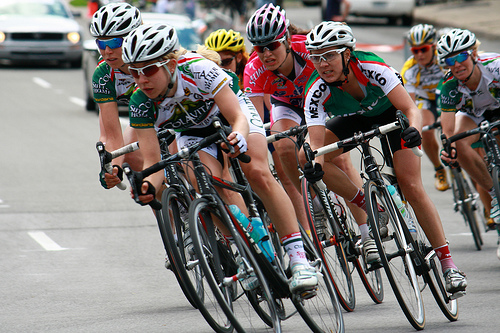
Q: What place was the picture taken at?
A: It was taken at the road.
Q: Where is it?
A: This is at the road.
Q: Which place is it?
A: It is a road.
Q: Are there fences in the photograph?
A: No, there are no fences.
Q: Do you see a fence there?
A: No, there are no fences.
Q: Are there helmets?
A: Yes, there is a helmet.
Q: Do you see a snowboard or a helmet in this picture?
A: Yes, there is a helmet.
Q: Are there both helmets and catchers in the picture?
A: No, there is a helmet but no catchers.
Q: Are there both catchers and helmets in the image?
A: No, there is a helmet but no catchers.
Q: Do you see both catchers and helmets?
A: No, there is a helmet but no catchers.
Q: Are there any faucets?
A: No, there are no faucets.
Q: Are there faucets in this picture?
A: No, there are no faucets.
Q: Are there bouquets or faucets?
A: No, there are no faucets or bouquets.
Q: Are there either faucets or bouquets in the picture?
A: No, there are no faucets or bouquets.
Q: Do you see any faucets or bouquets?
A: No, there are no faucets or bouquets.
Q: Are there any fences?
A: No, there are no fences.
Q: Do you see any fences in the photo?
A: No, there are no fences.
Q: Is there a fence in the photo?
A: No, there are no fences.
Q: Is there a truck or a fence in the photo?
A: No, there are no fences or trucks.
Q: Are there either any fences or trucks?
A: No, there are no fences or trucks.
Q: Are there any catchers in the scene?
A: No, there are no catchers.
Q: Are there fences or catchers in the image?
A: No, there are no catchers or fences.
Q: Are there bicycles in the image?
A: Yes, there is a bicycle.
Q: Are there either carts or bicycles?
A: Yes, there is a bicycle.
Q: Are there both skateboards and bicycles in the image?
A: No, there is a bicycle but no skateboards.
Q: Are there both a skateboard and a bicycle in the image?
A: No, there is a bicycle but no skateboards.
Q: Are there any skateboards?
A: No, there are no skateboards.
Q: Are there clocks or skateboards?
A: No, there are no skateboards or clocks.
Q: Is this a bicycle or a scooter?
A: This is a bicycle.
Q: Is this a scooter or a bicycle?
A: This is a bicycle.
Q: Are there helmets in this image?
A: Yes, there is a helmet.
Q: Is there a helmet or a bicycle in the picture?
A: Yes, there is a helmet.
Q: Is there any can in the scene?
A: No, there are no cans.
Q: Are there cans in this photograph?
A: No, there are no cans.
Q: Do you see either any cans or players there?
A: No, there are no cans or players.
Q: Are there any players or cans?
A: No, there are no cans or players.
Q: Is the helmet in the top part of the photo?
A: Yes, the helmet is in the top of the image.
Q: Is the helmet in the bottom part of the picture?
A: No, the helmet is in the top of the image.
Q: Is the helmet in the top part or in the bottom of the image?
A: The helmet is in the top of the image.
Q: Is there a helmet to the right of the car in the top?
A: Yes, there is a helmet to the right of the car.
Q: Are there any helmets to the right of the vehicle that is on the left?
A: Yes, there is a helmet to the right of the car.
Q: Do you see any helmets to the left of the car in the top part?
A: No, the helmet is to the right of the car.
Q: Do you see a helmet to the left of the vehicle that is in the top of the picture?
A: No, the helmet is to the right of the car.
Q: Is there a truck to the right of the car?
A: No, there is a helmet to the right of the car.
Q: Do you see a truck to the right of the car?
A: No, there is a helmet to the right of the car.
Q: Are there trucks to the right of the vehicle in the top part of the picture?
A: No, there is a helmet to the right of the car.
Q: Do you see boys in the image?
A: No, there are no boys.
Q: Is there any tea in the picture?
A: No, there is no tea.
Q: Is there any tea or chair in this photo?
A: No, there are no tea or chairs.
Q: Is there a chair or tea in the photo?
A: No, there are no tea or chairs.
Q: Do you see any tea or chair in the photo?
A: No, there are no tea or chairs.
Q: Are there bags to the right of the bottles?
A: No, there is a water bottle to the right of the bottles.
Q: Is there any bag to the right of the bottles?
A: No, there is a water bottle to the right of the bottles.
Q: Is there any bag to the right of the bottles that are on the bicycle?
A: No, there is a water bottle to the right of the bottles.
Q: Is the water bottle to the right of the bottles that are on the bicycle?
A: Yes, the water bottle is to the right of the bottles.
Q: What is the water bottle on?
A: The water bottle is on the bicycle.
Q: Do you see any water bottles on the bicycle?
A: Yes, there is a water bottle on the bicycle.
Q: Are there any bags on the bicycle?
A: No, there is a water bottle on the bicycle.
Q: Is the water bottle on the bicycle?
A: Yes, the water bottle is on the bicycle.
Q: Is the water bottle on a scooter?
A: No, the water bottle is on the bicycle.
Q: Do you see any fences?
A: No, there are no fences.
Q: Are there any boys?
A: No, there are no boys.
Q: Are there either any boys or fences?
A: No, there are no boys or fences.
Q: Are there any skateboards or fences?
A: No, there are no fences or skateboards.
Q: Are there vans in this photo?
A: No, there are no vans.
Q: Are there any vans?
A: No, there are no vans.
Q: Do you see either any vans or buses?
A: No, there are no vans or buses.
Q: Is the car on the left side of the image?
A: Yes, the car is on the left of the image.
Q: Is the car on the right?
A: No, the car is on the left of the image.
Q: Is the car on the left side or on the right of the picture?
A: The car is on the left of the image.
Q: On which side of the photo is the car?
A: The car is on the left of the image.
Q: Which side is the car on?
A: The car is on the left of the image.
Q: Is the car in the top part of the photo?
A: Yes, the car is in the top of the image.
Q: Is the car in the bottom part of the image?
A: No, the car is in the top of the image.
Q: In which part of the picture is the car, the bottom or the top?
A: The car is in the top of the image.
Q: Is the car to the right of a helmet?
A: No, the car is to the left of a helmet.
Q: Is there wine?
A: No, there is no wine.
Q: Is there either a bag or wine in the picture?
A: No, there are no wine or bags.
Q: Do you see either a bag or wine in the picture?
A: No, there are no wine or bags.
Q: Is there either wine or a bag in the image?
A: No, there are no wine or bags.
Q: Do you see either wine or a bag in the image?
A: No, there are no wine or bags.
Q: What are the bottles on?
A: The bottles are on the bicycle.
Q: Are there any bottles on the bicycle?
A: Yes, there are bottles on the bicycle.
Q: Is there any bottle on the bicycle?
A: Yes, there are bottles on the bicycle.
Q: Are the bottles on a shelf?
A: No, the bottles are on the bicycle.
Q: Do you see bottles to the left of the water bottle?
A: Yes, there are bottles to the left of the water bottle.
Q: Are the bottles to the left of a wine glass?
A: No, the bottles are to the left of the water bottle.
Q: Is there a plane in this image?
A: No, there are no airplanes.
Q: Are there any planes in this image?
A: No, there are no planes.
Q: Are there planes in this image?
A: No, there are no planes.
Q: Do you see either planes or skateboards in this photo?
A: No, there are no planes or skateboards.